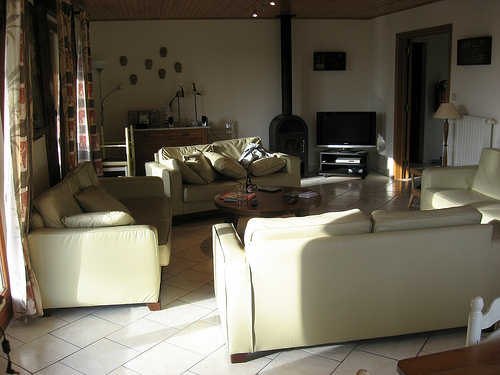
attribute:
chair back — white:
[467, 296, 499, 338]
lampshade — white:
[432, 99, 467, 121]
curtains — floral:
[3, 97, 45, 312]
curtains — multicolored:
[11, 24, 133, 189]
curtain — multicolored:
[54, 5, 105, 182]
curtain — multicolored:
[3, 1, 45, 318]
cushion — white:
[169, 157, 219, 172]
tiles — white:
[0, 160, 499, 374]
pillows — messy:
[161, 141, 288, 183]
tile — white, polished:
[103, 316, 180, 353]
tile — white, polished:
[61, 337, 141, 373]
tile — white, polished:
[256, 349, 342, 374]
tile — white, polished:
[328, 348, 400, 373]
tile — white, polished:
[164, 319, 226, 356]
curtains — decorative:
[3, 9, 103, 326]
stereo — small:
[125, 110, 172, 130]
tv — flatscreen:
[318, 111, 380, 147]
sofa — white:
[137, 123, 314, 230]